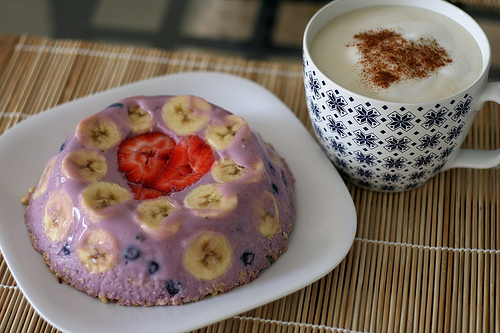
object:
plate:
[2, 71, 360, 332]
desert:
[23, 94, 300, 303]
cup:
[302, 0, 499, 193]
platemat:
[367, 198, 499, 332]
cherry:
[118, 129, 216, 200]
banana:
[184, 229, 237, 280]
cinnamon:
[352, 29, 453, 91]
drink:
[319, 7, 484, 101]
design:
[387, 107, 415, 167]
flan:
[24, 202, 290, 310]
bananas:
[62, 113, 131, 212]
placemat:
[362, 191, 500, 330]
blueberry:
[262, 157, 294, 200]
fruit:
[120, 135, 206, 195]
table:
[1, 30, 497, 332]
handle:
[449, 80, 500, 167]